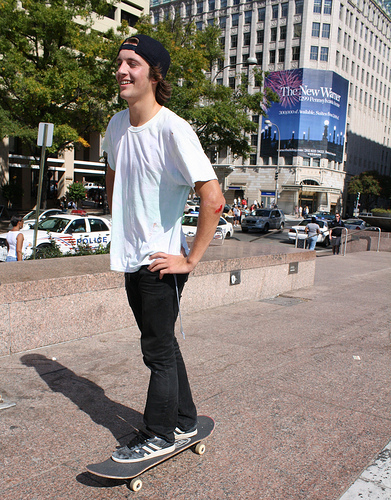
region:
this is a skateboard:
[70, 409, 221, 492]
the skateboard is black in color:
[98, 465, 120, 471]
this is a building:
[272, 6, 377, 204]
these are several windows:
[257, 10, 369, 51]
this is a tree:
[3, 5, 92, 212]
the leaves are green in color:
[22, 79, 58, 97]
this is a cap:
[118, 35, 170, 72]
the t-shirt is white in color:
[130, 183, 159, 224]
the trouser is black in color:
[152, 384, 174, 416]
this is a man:
[95, 31, 251, 461]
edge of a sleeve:
[182, 168, 210, 194]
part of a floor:
[282, 427, 311, 462]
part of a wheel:
[134, 482, 149, 498]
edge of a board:
[148, 453, 165, 471]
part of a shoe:
[128, 429, 162, 458]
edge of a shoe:
[148, 441, 164, 452]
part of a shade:
[75, 389, 113, 447]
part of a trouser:
[158, 408, 174, 427]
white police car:
[2, 213, 111, 256]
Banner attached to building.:
[265, 65, 347, 165]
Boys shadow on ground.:
[14, 349, 150, 446]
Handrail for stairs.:
[242, 223, 302, 249]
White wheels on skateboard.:
[90, 440, 209, 491]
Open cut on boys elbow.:
[200, 188, 229, 224]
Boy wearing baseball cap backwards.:
[118, 33, 169, 105]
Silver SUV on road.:
[238, 206, 287, 235]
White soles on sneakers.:
[108, 426, 202, 462]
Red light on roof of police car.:
[57, 207, 100, 217]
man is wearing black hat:
[85, 20, 194, 85]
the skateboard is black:
[59, 392, 201, 488]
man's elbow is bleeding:
[206, 197, 242, 223]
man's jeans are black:
[112, 264, 211, 491]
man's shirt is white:
[105, 105, 236, 284]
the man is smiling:
[100, 42, 168, 110]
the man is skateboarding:
[57, 22, 258, 485]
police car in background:
[8, 195, 120, 267]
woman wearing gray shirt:
[300, 208, 328, 242]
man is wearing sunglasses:
[327, 208, 345, 223]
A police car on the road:
[15, 211, 123, 267]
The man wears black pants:
[122, 268, 224, 453]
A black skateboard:
[105, 421, 227, 490]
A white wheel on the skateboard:
[126, 472, 143, 492]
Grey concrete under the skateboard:
[218, 377, 314, 459]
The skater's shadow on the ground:
[16, 339, 154, 448]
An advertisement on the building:
[256, 69, 353, 142]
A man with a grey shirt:
[300, 213, 323, 250]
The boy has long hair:
[106, 38, 173, 110]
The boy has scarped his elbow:
[211, 201, 226, 218]